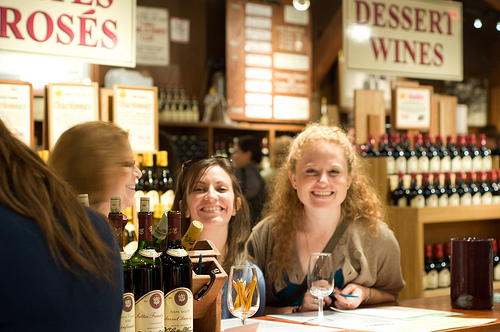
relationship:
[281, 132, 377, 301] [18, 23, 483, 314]
woman in photo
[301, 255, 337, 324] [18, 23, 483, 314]
glass in photo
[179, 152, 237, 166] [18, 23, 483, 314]
goggles on photo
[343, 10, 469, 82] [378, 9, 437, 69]
sign with letters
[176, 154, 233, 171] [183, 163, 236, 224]
sunglasses on head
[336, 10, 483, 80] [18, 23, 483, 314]
advertisement in photo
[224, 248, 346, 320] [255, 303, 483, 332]
glasses on counter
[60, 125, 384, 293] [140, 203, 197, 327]
women enjoying wine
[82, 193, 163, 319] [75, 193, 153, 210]
bottles with corks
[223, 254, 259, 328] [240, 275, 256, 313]
glass has pencils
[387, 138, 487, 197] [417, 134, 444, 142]
bottles has tops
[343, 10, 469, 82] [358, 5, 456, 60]
sign says dessert wines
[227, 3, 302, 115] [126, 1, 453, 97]
chart in background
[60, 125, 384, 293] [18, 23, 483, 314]
women in photo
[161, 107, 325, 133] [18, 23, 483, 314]
shelf in photo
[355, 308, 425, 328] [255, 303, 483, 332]
paper on counter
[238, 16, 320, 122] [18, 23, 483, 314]
signboard in photo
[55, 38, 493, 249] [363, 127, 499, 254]
store sell wines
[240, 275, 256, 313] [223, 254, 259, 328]
pencils in glass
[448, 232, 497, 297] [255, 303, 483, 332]
vessel on counter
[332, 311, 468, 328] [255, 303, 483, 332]
forms on counter